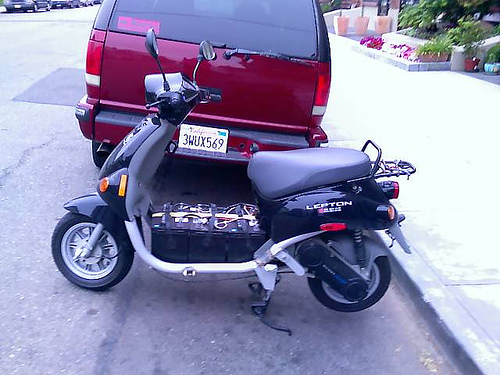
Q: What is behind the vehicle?
A: Scooter.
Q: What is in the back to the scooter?
A: Curb.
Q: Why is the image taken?
A: Remembrance.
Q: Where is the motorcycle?
A: Road.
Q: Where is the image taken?
A: On road.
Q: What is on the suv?
A: License.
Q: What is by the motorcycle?
A: Curb.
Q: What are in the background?
A: Flowers.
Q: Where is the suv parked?
A: Front of a moped.